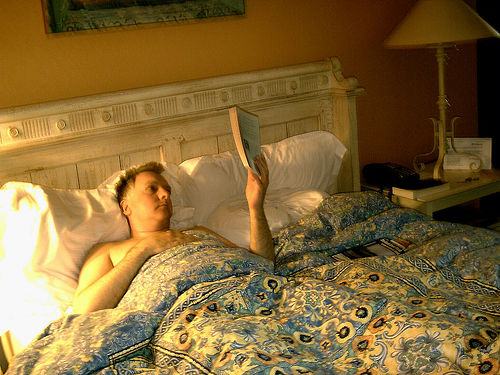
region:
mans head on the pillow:
[90, 151, 186, 232]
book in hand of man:
[220, 90, 281, 191]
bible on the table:
[385, 172, 455, 197]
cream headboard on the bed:
[0, 50, 361, 185]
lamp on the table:
[375, 5, 496, 175]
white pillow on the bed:
[180, 125, 345, 235]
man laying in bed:
[57, 95, 292, 327]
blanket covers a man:
[18, 216, 483, 363]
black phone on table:
[358, 151, 419, 189]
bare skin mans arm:
[88, 243, 131, 297]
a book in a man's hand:
[219, 106, 272, 188]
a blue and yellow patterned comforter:
[6, 185, 497, 374]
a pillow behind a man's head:
[5, 155, 187, 353]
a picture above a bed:
[35, 0, 251, 35]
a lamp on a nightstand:
[381, 0, 492, 180]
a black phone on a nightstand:
[360, 155, 415, 200]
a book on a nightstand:
[381, 171, 447, 196]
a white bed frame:
[0, 50, 365, 215]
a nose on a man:
[156, 186, 170, 200]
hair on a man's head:
[111, 159, 168, 202]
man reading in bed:
[7, 59, 498, 368]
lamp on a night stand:
[372, 0, 498, 192]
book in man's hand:
[214, 99, 278, 181]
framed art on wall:
[34, 0, 264, 38]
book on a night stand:
[386, 173, 453, 209]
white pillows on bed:
[169, 123, 363, 247]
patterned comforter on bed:
[182, 264, 483, 364]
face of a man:
[107, 157, 182, 234]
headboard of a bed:
[8, 66, 369, 141]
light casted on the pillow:
[2, 171, 62, 353]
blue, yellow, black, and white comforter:
[7, 192, 484, 374]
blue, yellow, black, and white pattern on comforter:
[163, 268, 358, 372]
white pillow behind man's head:
[15, 163, 188, 263]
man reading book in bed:
[55, 98, 284, 314]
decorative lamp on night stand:
[380, 4, 476, 184]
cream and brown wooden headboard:
[5, 61, 365, 204]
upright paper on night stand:
[442, 131, 490, 169]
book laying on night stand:
[394, 174, 454, 199]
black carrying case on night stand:
[362, 157, 418, 192]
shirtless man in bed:
[69, 133, 289, 335]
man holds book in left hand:
[78, 85, 318, 286]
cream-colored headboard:
[0, 53, 363, 276]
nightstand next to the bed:
[337, 0, 497, 235]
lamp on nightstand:
[336, 0, 496, 226]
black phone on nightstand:
[351, 107, 492, 214]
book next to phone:
[370, 141, 463, 222]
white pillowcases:
[4, 130, 400, 330]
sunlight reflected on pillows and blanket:
[5, 57, 233, 372]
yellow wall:
[3, 0, 475, 166]